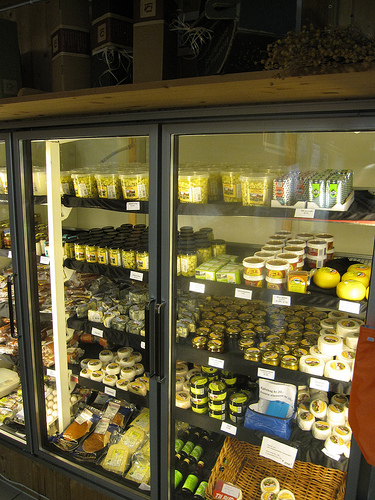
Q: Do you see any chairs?
A: No, there are no chairs.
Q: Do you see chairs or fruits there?
A: No, there are no chairs or fruits.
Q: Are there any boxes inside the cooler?
A: Yes, there are boxes inside the cooler.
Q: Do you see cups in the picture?
A: No, there are no cups.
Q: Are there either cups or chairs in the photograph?
A: No, there are no cups or chairs.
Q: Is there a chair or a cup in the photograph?
A: No, there are no cups or chairs.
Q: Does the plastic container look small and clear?
A: Yes, the container is small and clear.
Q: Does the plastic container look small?
A: Yes, the container is small.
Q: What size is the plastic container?
A: The container is small.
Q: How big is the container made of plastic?
A: The container is small.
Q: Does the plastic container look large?
A: No, the container is small.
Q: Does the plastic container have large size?
A: No, the container is small.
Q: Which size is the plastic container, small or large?
A: The container is small.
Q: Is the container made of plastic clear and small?
A: Yes, the container is clear and small.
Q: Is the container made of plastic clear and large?
A: No, the container is clear but small.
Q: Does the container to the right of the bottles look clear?
A: Yes, the container is clear.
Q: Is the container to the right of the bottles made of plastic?
A: Yes, the container is made of plastic.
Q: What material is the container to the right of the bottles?
A: The container is made of plastic.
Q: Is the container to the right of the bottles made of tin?
A: No, the container is made of plastic.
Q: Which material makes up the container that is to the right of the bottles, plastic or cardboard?
A: The container is made of plastic.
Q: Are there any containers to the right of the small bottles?
A: Yes, there is a container to the right of the bottles.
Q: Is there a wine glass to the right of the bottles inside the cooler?
A: No, there is a container to the right of the bottles.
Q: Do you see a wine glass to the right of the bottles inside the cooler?
A: No, there is a container to the right of the bottles.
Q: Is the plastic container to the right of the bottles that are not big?
A: Yes, the container is to the right of the bottles.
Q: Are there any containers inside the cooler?
A: Yes, there is a container inside the cooler.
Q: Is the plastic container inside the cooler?
A: Yes, the container is inside the cooler.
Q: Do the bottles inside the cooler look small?
A: Yes, the bottles are small.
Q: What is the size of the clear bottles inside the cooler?
A: The bottles are small.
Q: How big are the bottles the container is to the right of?
A: The bottles are small.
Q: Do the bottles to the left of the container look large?
A: No, the bottles are small.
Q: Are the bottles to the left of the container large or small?
A: The bottles are small.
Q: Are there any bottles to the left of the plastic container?
A: Yes, there are bottles to the left of the container.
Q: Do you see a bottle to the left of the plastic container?
A: Yes, there are bottles to the left of the container.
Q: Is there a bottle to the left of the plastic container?
A: Yes, there are bottles to the left of the container.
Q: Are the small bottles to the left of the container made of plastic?
A: Yes, the bottles are to the left of the container.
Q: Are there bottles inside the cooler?
A: Yes, there are bottles inside the cooler.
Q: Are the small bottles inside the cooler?
A: Yes, the bottles are inside the cooler.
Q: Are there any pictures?
A: No, there are no pictures.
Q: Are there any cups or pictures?
A: No, there are no pictures or cups.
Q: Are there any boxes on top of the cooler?
A: Yes, there is a box on top of the cooler.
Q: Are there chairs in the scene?
A: No, there are no chairs.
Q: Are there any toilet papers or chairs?
A: No, there are no chairs or toilet papers.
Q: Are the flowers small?
A: Yes, the flowers are small.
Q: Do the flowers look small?
A: Yes, the flowers are small.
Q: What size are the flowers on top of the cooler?
A: The flowers are small.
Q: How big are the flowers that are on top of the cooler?
A: The flowers are small.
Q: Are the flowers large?
A: No, the flowers are small.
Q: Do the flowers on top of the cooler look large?
A: No, the flowers are small.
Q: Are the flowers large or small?
A: The flowers are small.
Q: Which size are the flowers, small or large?
A: The flowers are small.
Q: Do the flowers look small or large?
A: The flowers are small.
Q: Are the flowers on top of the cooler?
A: Yes, the flowers are on top of the cooler.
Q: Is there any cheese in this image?
A: Yes, there is cheese.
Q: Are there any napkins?
A: No, there are no napkins.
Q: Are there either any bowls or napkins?
A: No, there are no napkins or bowls.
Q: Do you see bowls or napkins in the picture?
A: No, there are no napkins or bowls.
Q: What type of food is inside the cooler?
A: The food is cheese.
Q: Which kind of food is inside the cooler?
A: The food is cheese.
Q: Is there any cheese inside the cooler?
A: Yes, there is cheese inside the cooler.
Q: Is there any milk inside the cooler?
A: No, there is cheese inside the cooler.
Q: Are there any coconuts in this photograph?
A: No, there are no coconuts.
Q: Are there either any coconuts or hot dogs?
A: No, there are no coconuts or hot dogs.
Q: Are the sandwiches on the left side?
A: Yes, the sandwiches are on the left of the image.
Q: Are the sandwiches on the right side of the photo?
A: No, the sandwiches are on the left of the image.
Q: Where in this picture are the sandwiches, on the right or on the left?
A: The sandwiches are on the left of the image.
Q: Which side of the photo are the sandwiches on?
A: The sandwiches are on the left of the image.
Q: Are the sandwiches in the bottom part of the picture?
A: Yes, the sandwiches are in the bottom of the image.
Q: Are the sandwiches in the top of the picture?
A: No, the sandwiches are in the bottom of the image.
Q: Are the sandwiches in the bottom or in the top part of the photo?
A: The sandwiches are in the bottom of the image.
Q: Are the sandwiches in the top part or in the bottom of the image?
A: The sandwiches are in the bottom of the image.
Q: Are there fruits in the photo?
A: No, there are no fruits.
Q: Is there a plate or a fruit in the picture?
A: No, there are no fruits or plates.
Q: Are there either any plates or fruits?
A: No, there are no fruits or plates.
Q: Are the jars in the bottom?
A: Yes, the jars are in the bottom of the image.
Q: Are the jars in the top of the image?
A: No, the jars are in the bottom of the image.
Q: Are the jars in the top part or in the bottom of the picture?
A: The jars are in the bottom of the image.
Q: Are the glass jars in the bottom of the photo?
A: Yes, the jars are in the bottom of the image.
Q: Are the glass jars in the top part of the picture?
A: No, the jars are in the bottom of the image.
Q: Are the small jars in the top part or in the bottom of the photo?
A: The jars are in the bottom of the image.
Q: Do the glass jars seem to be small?
A: Yes, the jars are small.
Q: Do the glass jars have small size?
A: Yes, the jars are small.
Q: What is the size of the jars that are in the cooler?
A: The jars are small.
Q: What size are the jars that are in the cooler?
A: The jars are small.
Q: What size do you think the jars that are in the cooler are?
A: The jars are small.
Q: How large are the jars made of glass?
A: The jars are small.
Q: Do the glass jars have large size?
A: No, the jars are small.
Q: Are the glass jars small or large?
A: The jars are small.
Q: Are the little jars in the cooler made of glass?
A: Yes, the jars are made of glass.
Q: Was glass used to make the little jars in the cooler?
A: Yes, the jars are made of glass.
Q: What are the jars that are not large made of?
A: The jars are made of glass.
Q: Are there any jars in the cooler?
A: Yes, there are jars in the cooler.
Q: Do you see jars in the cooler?
A: Yes, there are jars in the cooler.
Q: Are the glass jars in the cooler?
A: Yes, the jars are in the cooler.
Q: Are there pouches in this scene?
A: Yes, there is a pouch.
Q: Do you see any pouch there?
A: Yes, there is a pouch.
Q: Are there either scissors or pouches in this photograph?
A: Yes, there is a pouch.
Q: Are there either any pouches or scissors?
A: Yes, there is a pouch.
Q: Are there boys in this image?
A: No, there are no boys.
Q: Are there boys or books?
A: No, there are no boys or books.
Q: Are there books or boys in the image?
A: No, there are no boys or books.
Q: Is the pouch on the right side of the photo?
A: Yes, the pouch is on the right of the image.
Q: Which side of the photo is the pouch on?
A: The pouch is on the right of the image.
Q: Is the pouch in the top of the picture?
A: No, the pouch is in the bottom of the image.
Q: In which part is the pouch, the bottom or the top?
A: The pouch is in the bottom of the image.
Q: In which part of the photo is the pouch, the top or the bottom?
A: The pouch is in the bottom of the image.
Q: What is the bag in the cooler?
A: The bag is a pouch.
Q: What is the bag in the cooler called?
A: The bag is a pouch.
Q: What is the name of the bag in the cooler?
A: The bag is a pouch.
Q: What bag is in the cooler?
A: The bag is a pouch.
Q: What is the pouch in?
A: The pouch is in the cooler.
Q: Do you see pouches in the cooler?
A: Yes, there is a pouch in the cooler.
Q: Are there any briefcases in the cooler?
A: No, there is a pouch in the cooler.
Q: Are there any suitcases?
A: No, there are no suitcases.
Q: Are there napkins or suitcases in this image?
A: No, there are no suitcases or napkins.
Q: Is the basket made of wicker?
A: Yes, the basket is made of wicker.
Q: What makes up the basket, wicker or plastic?
A: The basket is made of wicker.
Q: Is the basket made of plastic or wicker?
A: The basket is made of wicker.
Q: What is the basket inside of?
A: The basket is inside the cooler.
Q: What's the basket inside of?
A: The basket is inside the cooler.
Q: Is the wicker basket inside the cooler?
A: Yes, the basket is inside the cooler.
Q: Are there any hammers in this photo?
A: No, there are no hammers.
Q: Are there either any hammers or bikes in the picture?
A: No, there are no hammers or bikes.